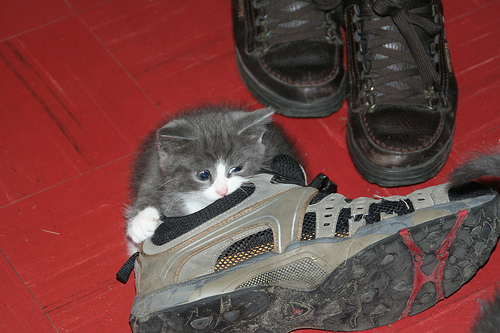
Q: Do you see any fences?
A: No, there are no fences.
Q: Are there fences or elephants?
A: No, there are no fences or elephants.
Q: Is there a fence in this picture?
A: No, there are no fences.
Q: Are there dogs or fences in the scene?
A: No, there are no fences or dogs.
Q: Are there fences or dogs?
A: No, there are no fences or dogs.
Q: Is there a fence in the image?
A: No, there are no fences.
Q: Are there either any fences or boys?
A: No, there are no fences or boys.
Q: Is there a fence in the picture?
A: No, there are no fences.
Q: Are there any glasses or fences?
A: No, there are no fences or glasses.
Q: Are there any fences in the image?
A: No, there are no fences.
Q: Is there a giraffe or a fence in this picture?
A: No, there are no fences or giraffes.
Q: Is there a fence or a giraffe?
A: No, there are no fences or giraffes.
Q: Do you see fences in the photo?
A: No, there are no fences.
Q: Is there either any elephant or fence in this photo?
A: No, there are no fences or elephants.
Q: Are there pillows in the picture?
A: No, there are no pillows.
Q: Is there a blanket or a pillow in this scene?
A: No, there are no pillows or blankets.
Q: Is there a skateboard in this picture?
A: No, there are no skateboards.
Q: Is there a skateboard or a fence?
A: No, there are no skateboards or fences.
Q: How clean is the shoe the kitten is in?
A: The shoe is dirty.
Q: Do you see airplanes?
A: No, there are no airplanes.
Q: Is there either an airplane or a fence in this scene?
A: No, there are no airplanes or fences.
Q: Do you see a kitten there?
A: Yes, there is a kitten.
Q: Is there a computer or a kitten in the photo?
A: Yes, there is a kitten.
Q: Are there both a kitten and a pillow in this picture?
A: No, there is a kitten but no pillows.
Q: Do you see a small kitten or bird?
A: Yes, there is a small kitten.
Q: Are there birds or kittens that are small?
A: Yes, the kitten is small.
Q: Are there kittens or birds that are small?
A: Yes, the kitten is small.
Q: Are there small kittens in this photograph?
A: Yes, there is a small kitten.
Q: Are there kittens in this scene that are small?
A: Yes, there is a kitten that is small.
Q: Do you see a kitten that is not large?
A: Yes, there is a small kitten.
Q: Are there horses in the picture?
A: No, there are no horses.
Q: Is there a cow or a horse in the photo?
A: No, there are no horses or cows.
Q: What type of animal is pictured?
A: The animal is a kitten.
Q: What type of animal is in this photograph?
A: The animal is a kitten.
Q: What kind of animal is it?
A: The animal is a kitten.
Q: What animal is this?
A: This is a kitten.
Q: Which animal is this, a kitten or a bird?
A: This is a kitten.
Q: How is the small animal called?
A: The animal is a kitten.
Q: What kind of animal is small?
A: The animal is a kitten.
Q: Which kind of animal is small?
A: The animal is a kitten.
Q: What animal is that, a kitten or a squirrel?
A: That is a kitten.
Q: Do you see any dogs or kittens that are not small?
A: No, there is a kitten but it is small.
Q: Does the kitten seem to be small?
A: Yes, the kitten is small.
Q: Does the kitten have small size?
A: Yes, the kitten is small.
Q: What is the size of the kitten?
A: The kitten is small.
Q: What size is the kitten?
A: The kitten is small.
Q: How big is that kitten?
A: The kitten is small.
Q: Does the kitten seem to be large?
A: No, the kitten is small.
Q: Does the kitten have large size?
A: No, the kitten is small.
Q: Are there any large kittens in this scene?
A: No, there is a kitten but it is small.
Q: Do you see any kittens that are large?
A: No, there is a kitten but it is small.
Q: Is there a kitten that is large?
A: No, there is a kitten but it is small.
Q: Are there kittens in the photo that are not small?
A: No, there is a kitten but it is small.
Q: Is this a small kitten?
A: Yes, this is a small kitten.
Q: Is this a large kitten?
A: No, this is a small kitten.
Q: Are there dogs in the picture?
A: No, there are no dogs.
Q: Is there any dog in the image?
A: No, there are no dogs.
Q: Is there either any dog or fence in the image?
A: No, there are no dogs or fences.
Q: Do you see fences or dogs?
A: No, there are no dogs or fences.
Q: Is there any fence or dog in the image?
A: No, there are no dogs or fences.